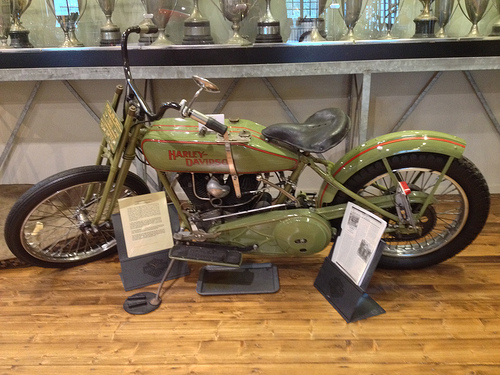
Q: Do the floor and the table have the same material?
A: No, the floor is made of wood and the table is made of metal.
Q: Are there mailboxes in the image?
A: No, there are no mailboxes.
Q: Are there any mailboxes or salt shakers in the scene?
A: No, there are no mailboxes or salt shakers.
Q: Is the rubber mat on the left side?
A: Yes, the mat is on the left of the image.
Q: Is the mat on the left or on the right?
A: The mat is on the left of the image.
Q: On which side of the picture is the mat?
A: The mat is on the left of the image.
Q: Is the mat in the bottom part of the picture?
A: Yes, the mat is in the bottom of the image.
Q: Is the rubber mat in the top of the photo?
A: No, the mat is in the bottom of the image.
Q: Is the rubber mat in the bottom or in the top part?
A: The mat is in the bottom of the image.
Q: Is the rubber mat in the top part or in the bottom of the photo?
A: The mat is in the bottom of the image.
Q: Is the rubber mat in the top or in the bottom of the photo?
A: The mat is in the bottom of the image.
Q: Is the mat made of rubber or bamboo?
A: The mat is made of rubber.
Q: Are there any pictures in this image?
A: No, there are no pictures.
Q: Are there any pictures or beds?
A: No, there are no pictures or beds.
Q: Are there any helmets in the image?
A: No, there are no helmets.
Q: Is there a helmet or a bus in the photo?
A: No, there are no helmets or buses.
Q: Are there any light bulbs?
A: No, there are no light bulbs.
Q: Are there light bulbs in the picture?
A: No, there are no light bulbs.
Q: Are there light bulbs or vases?
A: No, there are no light bulbs or vases.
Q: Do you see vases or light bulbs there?
A: No, there are no light bulbs or vases.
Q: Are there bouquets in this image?
A: No, there are no bouquets.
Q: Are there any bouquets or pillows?
A: No, there are no bouquets or pillows.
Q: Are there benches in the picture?
A: No, there are no benches.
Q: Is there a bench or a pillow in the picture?
A: No, there are no benches or pillows.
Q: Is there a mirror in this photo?
A: Yes, there is a mirror.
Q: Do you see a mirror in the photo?
A: Yes, there is a mirror.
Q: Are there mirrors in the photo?
A: Yes, there is a mirror.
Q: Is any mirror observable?
A: Yes, there is a mirror.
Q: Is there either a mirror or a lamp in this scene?
A: Yes, there is a mirror.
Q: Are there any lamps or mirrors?
A: Yes, there is a mirror.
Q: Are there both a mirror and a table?
A: Yes, there are both a mirror and a table.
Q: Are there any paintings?
A: No, there are no paintings.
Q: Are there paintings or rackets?
A: No, there are no paintings or rackets.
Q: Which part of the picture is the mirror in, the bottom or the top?
A: The mirror is in the top of the image.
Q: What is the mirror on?
A: The mirror is on the motorbike.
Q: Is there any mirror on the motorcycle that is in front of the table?
A: Yes, there is a mirror on the motorbike.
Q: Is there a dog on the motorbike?
A: No, there is a mirror on the motorbike.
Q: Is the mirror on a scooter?
A: No, the mirror is on a motorcycle.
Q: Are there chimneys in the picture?
A: No, there are no chimneys.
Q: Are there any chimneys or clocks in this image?
A: No, there are no chimneys or clocks.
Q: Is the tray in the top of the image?
A: No, the tray is in the bottom of the image.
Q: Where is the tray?
A: The tray is on the floor.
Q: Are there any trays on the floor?
A: Yes, there is a tray on the floor.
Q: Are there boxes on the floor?
A: No, there is a tray on the floor.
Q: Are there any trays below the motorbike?
A: Yes, there is a tray below the motorbike.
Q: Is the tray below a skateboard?
A: No, the tray is below the motorbike.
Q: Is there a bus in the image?
A: No, there are no buses.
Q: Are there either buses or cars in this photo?
A: No, there are no buses or cars.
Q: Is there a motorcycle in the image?
A: Yes, there is a motorcycle.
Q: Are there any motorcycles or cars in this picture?
A: Yes, there is a motorcycle.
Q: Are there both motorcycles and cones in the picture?
A: No, there is a motorcycle but no cones.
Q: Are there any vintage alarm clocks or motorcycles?
A: Yes, there is a vintage motorcycle.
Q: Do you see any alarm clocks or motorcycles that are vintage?
A: Yes, the motorcycle is vintage.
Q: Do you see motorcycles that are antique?
A: Yes, there is an antique motorcycle.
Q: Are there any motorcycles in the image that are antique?
A: Yes, there is a motorcycle that is antique.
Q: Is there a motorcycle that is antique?
A: Yes, there is a motorcycle that is antique.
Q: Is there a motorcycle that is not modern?
A: Yes, there is a antique motorcycle.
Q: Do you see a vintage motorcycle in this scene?
A: Yes, there is a vintage motorcycle.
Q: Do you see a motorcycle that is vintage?
A: Yes, there is a motorcycle that is vintage.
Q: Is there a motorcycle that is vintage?
A: Yes, there is a motorcycle that is vintage.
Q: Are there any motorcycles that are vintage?
A: Yes, there is a motorcycle that is vintage.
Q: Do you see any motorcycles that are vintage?
A: Yes, there is a motorcycle that is vintage.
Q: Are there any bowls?
A: No, there are no bowls.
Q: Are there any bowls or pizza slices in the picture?
A: No, there are no bowls or pizza slices.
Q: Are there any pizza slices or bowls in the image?
A: No, there are no bowls or pizza slices.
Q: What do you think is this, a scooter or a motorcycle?
A: This is a motorcycle.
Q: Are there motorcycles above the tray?
A: Yes, there is a motorcycle above the tray.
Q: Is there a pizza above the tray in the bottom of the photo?
A: No, there is a motorcycle above the tray.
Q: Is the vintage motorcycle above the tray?
A: Yes, the motorcycle is above the tray.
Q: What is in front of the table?
A: The motorcycle is in front of the table.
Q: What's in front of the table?
A: The motorcycle is in front of the table.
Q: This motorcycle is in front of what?
A: The motorcycle is in front of the table.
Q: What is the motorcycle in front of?
A: The motorcycle is in front of the table.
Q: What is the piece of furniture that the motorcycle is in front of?
A: The piece of furniture is a table.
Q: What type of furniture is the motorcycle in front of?
A: The motorcycle is in front of the table.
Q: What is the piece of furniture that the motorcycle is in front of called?
A: The piece of furniture is a table.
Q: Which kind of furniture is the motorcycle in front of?
A: The motorcycle is in front of the table.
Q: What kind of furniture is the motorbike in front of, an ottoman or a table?
A: The motorbike is in front of a table.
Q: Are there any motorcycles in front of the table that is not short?
A: Yes, there is a motorcycle in front of the table.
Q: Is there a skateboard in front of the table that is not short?
A: No, there is a motorcycle in front of the table.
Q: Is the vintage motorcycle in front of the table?
A: Yes, the motorcycle is in front of the table.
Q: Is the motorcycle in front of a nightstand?
A: No, the motorcycle is in front of the table.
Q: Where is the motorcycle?
A: The motorcycle is on the floor.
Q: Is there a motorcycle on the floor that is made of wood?
A: Yes, there is a motorcycle on the floor.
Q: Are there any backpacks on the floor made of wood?
A: No, there is a motorcycle on the floor.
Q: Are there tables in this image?
A: Yes, there is a table.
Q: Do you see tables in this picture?
A: Yes, there is a table.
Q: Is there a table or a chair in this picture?
A: Yes, there is a table.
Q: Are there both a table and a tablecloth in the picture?
A: No, there is a table but no tablecloths.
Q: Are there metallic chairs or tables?
A: Yes, there is a metal table.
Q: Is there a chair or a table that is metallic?
A: Yes, the table is metallic.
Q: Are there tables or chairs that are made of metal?
A: Yes, the table is made of metal.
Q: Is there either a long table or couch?
A: Yes, there is a long table.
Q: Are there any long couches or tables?
A: Yes, there is a long table.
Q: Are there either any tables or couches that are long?
A: Yes, the table is long.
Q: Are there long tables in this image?
A: Yes, there is a long table.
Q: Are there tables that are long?
A: Yes, there is a table that is long.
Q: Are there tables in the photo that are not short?
A: Yes, there is a long table.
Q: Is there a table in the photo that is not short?
A: Yes, there is a long table.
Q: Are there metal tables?
A: Yes, there is a metal table.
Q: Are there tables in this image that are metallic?
A: Yes, there is a table that is metallic.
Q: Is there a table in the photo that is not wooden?
A: Yes, there is a metallic table.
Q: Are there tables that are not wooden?
A: Yes, there is a metallic table.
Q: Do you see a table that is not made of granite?
A: Yes, there is a table that is made of metal.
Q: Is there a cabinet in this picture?
A: No, there are no cabinets.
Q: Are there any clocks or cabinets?
A: No, there are no cabinets or clocks.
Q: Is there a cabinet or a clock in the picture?
A: No, there are no cabinets or clocks.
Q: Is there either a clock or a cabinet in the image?
A: No, there are no cabinets or clocks.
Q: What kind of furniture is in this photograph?
A: The furniture is a table.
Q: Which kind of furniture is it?
A: The piece of furniture is a table.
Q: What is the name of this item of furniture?
A: That is a table.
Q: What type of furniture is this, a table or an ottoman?
A: That is a table.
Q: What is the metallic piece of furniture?
A: The piece of furniture is a table.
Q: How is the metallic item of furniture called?
A: The piece of furniture is a table.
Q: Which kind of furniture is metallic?
A: The furniture is a table.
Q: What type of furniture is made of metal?
A: The furniture is a table.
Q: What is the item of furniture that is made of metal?
A: The piece of furniture is a table.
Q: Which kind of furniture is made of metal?
A: The furniture is a table.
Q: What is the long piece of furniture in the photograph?
A: The piece of furniture is a table.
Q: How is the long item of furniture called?
A: The piece of furniture is a table.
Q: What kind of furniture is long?
A: The furniture is a table.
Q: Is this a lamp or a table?
A: This is a table.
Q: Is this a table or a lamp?
A: This is a table.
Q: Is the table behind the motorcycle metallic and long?
A: Yes, the table is metallic and long.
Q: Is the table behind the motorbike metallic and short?
A: No, the table is metallic but long.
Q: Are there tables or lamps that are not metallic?
A: No, there is a table but it is metallic.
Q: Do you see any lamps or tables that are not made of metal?
A: No, there is a table but it is made of metal.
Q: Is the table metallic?
A: Yes, the table is metallic.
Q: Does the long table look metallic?
A: Yes, the table is metallic.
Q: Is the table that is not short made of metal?
A: Yes, the table is made of metal.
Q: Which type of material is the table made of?
A: The table is made of metal.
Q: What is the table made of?
A: The table is made of metal.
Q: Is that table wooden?
A: No, the table is metallic.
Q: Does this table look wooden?
A: No, the table is metallic.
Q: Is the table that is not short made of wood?
A: No, the table is made of metal.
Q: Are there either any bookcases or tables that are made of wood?
A: No, there is a table but it is made of metal.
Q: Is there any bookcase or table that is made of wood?
A: No, there is a table but it is made of metal.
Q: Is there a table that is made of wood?
A: No, there is a table but it is made of metal.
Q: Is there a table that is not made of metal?
A: No, there is a table but it is made of metal.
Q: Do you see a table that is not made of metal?
A: No, there is a table but it is made of metal.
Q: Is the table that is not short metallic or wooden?
A: The table is metallic.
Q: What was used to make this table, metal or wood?
A: The table is made of metal.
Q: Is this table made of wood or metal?
A: The table is made of metal.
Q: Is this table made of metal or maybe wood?
A: The table is made of metal.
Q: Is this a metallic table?
A: Yes, this is a metallic table.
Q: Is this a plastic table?
A: No, this is a metallic table.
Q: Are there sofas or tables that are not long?
A: No, there is a table but it is long.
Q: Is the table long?
A: Yes, the table is long.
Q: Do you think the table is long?
A: Yes, the table is long.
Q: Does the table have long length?
A: Yes, the table is long.